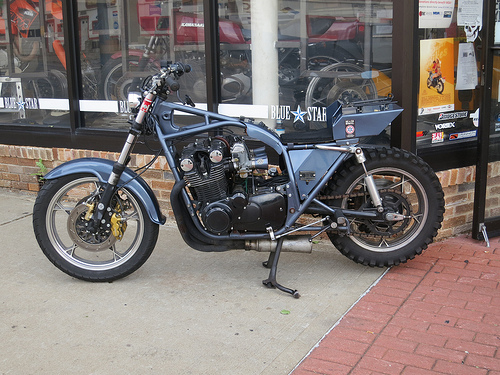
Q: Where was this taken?
A: On a sidewalk.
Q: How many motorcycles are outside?
A: One.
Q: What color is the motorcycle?
A: Dark blue.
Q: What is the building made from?
A: Brick.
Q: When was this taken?
A: During the day.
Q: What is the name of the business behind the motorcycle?
A: Blue Star.